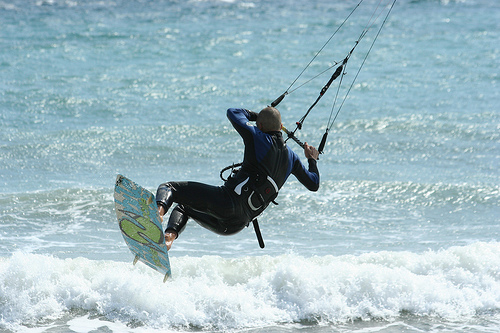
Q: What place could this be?
A: It is an ocean.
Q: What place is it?
A: It is an ocean.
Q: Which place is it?
A: It is an ocean.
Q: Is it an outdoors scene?
A: Yes, it is outdoors.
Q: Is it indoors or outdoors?
A: It is outdoors.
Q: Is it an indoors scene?
A: No, it is outdoors.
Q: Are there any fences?
A: No, there are no fences.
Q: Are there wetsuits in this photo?
A: Yes, there is a wetsuit.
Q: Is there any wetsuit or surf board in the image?
A: Yes, there is a wetsuit.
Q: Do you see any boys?
A: No, there are no boys.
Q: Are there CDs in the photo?
A: No, there are no cds.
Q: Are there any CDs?
A: No, there are no cds.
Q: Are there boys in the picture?
A: No, there are no boys.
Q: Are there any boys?
A: No, there are no boys.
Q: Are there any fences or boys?
A: No, there are no boys or fences.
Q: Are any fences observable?
A: No, there are no fences.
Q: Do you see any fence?
A: No, there are no fences.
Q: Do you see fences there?
A: No, there are no fences.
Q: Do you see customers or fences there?
A: No, there are no fences or customers.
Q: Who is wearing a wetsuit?
A: The man is wearing a wetsuit.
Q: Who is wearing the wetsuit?
A: The man is wearing a wetsuit.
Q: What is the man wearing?
A: The man is wearing a wetsuit.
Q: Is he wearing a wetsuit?
A: Yes, the man is wearing a wetsuit.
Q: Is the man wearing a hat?
A: No, the man is wearing a wetsuit.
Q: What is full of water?
A: The ocean is full of water.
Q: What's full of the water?
A: The ocean is full of water.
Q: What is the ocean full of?
A: The ocean is full of water.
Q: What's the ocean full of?
A: The ocean is full of water.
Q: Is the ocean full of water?
A: Yes, the ocean is full of water.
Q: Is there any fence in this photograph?
A: No, there are no fences.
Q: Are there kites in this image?
A: Yes, there is a kite.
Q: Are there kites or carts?
A: Yes, there is a kite.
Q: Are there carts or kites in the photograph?
A: Yes, there is a kite.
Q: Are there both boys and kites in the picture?
A: No, there is a kite but no boys.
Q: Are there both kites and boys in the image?
A: No, there is a kite but no boys.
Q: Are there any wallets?
A: No, there are no wallets.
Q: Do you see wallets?
A: No, there are no wallets.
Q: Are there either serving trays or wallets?
A: No, there are no wallets or serving trays.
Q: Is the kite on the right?
A: Yes, the kite is on the right of the image.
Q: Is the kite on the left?
A: No, the kite is on the right of the image.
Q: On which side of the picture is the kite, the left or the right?
A: The kite is on the right of the image.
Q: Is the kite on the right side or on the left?
A: The kite is on the right of the image.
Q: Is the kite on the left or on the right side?
A: The kite is on the right of the image.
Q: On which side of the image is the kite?
A: The kite is on the right of the image.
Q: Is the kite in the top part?
A: Yes, the kite is in the top of the image.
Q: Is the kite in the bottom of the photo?
A: No, the kite is in the top of the image.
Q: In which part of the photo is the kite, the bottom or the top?
A: The kite is in the top of the image.